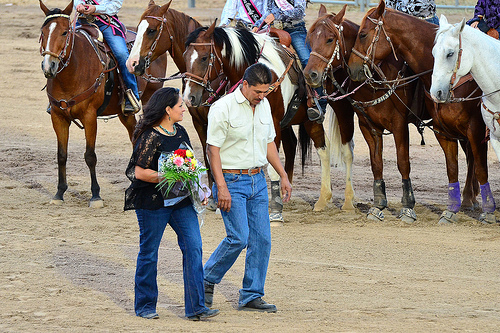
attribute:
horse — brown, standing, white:
[39, 4, 432, 228]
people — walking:
[125, 59, 287, 319]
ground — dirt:
[1, 10, 497, 333]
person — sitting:
[74, 1, 329, 121]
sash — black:
[242, 2, 266, 34]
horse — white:
[431, 13, 499, 121]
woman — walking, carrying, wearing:
[120, 86, 218, 323]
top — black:
[127, 128, 199, 212]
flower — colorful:
[155, 151, 210, 217]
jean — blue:
[203, 175, 280, 302]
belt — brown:
[223, 164, 278, 180]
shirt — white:
[207, 91, 274, 172]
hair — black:
[125, 87, 178, 165]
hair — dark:
[246, 61, 274, 88]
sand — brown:
[7, 58, 499, 329]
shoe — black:
[200, 278, 282, 320]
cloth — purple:
[448, 177, 491, 206]